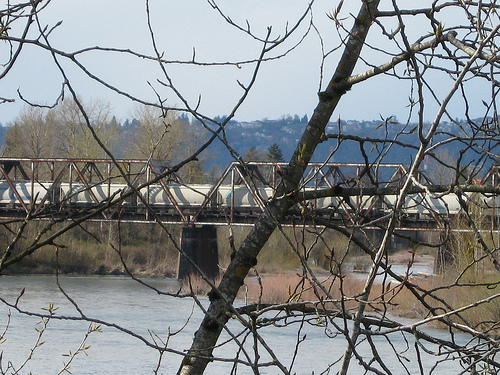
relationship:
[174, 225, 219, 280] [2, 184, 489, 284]
base on bridge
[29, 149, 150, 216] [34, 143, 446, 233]
railing along bridge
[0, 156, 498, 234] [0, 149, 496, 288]
fence along bridge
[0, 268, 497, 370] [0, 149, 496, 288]
water under bridge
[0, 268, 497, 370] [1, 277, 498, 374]
water in river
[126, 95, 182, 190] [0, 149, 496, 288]
tree beyond bridge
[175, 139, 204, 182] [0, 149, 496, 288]
tree beyond bridge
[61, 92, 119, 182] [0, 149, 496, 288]
tree beyond bridge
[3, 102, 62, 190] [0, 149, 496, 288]
tree beyond bridge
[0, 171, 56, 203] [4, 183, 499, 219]
car on train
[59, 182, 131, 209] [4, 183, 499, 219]
car on train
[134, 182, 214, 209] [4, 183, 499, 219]
car on train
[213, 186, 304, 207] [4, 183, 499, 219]
car on train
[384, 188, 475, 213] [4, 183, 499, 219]
car on train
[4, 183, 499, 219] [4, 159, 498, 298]
train on bridge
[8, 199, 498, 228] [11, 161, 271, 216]
train tracks are on bridge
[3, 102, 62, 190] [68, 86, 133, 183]
tree has branch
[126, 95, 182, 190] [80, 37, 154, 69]
tree has branch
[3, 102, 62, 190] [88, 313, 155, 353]
tree has branch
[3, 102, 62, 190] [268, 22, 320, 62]
tree has branch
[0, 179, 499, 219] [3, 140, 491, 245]
train on bridge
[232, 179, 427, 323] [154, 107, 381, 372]
bark of branch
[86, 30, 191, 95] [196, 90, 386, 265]
twig on tree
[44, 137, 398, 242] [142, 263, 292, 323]
photo taken in autum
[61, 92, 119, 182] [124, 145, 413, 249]
tree are behind bridge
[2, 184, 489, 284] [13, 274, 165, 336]
bridge over water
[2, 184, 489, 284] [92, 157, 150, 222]
bridge nas railing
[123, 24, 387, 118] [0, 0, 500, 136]
clouds are in sky